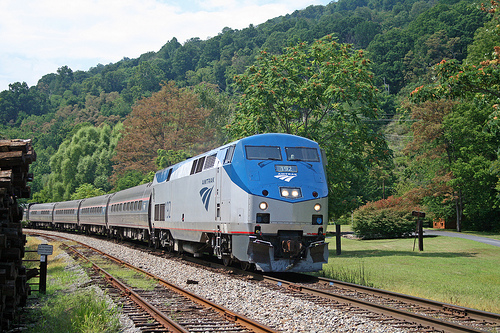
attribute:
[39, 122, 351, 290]
train — grey, blue, silver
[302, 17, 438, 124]
trees — green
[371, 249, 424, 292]
grass — green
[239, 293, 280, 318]
stones — concrete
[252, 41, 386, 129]
tree — bushy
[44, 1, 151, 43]
clouds — white, puffy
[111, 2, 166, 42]
sky — white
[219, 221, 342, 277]
train engine — silver, blue, large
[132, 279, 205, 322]
train track — empty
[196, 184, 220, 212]
logo — blue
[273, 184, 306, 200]
headlights — white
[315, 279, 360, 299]
tracks — rusty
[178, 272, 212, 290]
gravel — grey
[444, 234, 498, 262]
field — green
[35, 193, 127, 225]
cars — grey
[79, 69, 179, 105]
forest — green, tall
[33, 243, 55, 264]
sign post — small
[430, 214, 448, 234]
object — orange